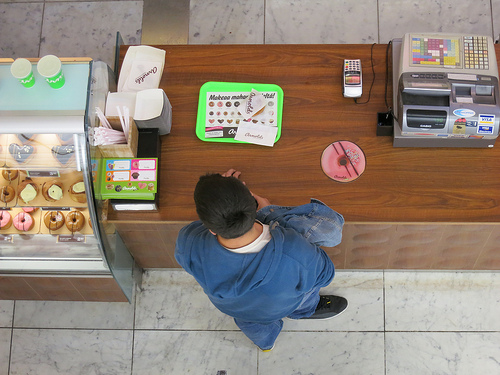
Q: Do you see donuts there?
A: Yes, there is a donut.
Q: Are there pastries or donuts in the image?
A: Yes, there is a donut.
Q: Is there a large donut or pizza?
A: Yes, there is a large donut.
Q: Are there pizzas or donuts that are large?
A: Yes, the donut is large.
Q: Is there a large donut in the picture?
A: Yes, there is a large donut.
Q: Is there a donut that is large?
A: Yes, there is a donut that is large.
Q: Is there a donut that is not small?
A: Yes, there is a large donut.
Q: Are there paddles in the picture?
A: No, there are no paddles.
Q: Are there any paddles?
A: No, there are no paddles.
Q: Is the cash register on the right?
A: Yes, the cash register is on the right of the image.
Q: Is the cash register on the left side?
A: No, the cash register is on the right of the image.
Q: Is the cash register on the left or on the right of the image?
A: The cash register is on the right of the image.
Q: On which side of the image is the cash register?
A: The cash register is on the right of the image.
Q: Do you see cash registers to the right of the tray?
A: Yes, there is a cash register to the right of the tray.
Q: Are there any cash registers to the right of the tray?
A: Yes, there is a cash register to the right of the tray.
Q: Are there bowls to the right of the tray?
A: No, there is a cash register to the right of the tray.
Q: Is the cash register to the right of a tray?
A: Yes, the cash register is to the right of a tray.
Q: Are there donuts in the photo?
A: Yes, there is a donut.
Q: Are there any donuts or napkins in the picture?
A: Yes, there is a donut.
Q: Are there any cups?
A: Yes, there is a cup.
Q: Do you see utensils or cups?
A: Yes, there is a cup.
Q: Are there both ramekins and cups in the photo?
A: No, there is a cup but no ramekins.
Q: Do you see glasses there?
A: No, there are no glasses.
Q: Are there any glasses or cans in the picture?
A: No, there are no glasses or cans.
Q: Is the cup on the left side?
A: Yes, the cup is on the left of the image.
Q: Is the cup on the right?
A: No, the cup is on the left of the image.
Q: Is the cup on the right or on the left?
A: The cup is on the left of the image.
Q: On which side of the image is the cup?
A: The cup is on the left of the image.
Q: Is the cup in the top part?
A: Yes, the cup is in the top of the image.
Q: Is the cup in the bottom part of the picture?
A: No, the cup is in the top of the image.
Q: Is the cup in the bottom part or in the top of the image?
A: The cup is in the top of the image.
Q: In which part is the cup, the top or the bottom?
A: The cup is in the top of the image.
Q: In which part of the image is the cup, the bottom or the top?
A: The cup is in the top of the image.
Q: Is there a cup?
A: Yes, there is a cup.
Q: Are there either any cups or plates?
A: Yes, there is a cup.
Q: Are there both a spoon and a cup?
A: No, there is a cup but no spoons.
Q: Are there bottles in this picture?
A: No, there are no bottles.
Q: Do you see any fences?
A: No, there are no fences.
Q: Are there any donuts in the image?
A: Yes, there is a donut.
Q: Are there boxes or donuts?
A: Yes, there is a donut.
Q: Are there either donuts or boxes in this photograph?
A: Yes, there is a donut.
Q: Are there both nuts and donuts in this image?
A: No, there is a donut but no nuts.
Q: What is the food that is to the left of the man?
A: The food is a donut.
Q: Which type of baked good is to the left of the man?
A: The food is a donut.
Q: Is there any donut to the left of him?
A: Yes, there is a donut to the left of the man.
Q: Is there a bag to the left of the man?
A: No, there is a donut to the left of the man.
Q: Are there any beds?
A: No, there are no beds.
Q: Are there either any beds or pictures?
A: No, there are no beds or pictures.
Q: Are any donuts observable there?
A: Yes, there is a donut.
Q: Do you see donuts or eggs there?
A: Yes, there is a donut.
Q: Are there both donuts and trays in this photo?
A: Yes, there are both a donut and a tray.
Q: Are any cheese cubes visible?
A: No, there are no cheese cubes.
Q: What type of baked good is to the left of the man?
A: The food is a donut.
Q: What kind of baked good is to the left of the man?
A: The food is a donut.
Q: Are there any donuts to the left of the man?
A: Yes, there is a donut to the left of the man.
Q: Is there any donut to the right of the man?
A: No, the donut is to the left of the man.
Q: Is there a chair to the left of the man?
A: No, there is a donut to the left of the man.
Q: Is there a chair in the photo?
A: No, there are no chairs.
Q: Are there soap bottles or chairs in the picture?
A: No, there are no chairs or soap bottles.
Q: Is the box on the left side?
A: Yes, the box is on the left of the image.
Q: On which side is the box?
A: The box is on the left of the image.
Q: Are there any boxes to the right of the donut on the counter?
A: Yes, there is a box to the right of the donut.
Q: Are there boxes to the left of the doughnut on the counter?
A: No, the box is to the right of the doughnut.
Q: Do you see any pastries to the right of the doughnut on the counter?
A: No, there is a box to the right of the donut.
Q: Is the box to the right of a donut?
A: Yes, the box is to the right of a donut.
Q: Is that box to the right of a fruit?
A: No, the box is to the right of a donut.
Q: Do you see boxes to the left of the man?
A: Yes, there is a box to the left of the man.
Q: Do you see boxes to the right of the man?
A: No, the box is to the left of the man.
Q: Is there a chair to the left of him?
A: No, there is a box to the left of the man.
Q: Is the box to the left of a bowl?
A: No, the box is to the left of the man.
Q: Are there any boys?
A: No, there are no boys.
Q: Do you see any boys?
A: No, there are no boys.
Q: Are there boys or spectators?
A: No, there are no boys or spectators.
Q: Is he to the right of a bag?
A: No, the man is to the right of the doughnut.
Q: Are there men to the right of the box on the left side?
A: Yes, there is a man to the right of the box.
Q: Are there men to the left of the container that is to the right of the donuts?
A: No, the man is to the right of the box.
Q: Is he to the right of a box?
A: Yes, the man is to the right of a box.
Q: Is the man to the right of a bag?
A: No, the man is to the right of a box.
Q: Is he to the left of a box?
A: No, the man is to the right of a box.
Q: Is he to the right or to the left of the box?
A: The man is to the right of the box.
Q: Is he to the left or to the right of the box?
A: The man is to the right of the box.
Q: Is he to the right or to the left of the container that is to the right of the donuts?
A: The man is to the right of the box.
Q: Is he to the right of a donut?
A: Yes, the man is to the right of a donut.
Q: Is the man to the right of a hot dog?
A: No, the man is to the right of a donut.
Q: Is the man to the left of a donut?
A: No, the man is to the right of a donut.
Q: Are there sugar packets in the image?
A: No, there are no sugar packets.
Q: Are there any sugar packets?
A: No, there are no sugar packets.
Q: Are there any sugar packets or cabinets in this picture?
A: No, there are no sugar packets or cabinets.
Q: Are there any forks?
A: No, there are no forks.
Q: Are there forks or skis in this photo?
A: No, there are no forks or skis.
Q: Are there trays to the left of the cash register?
A: Yes, there is a tray to the left of the cash register.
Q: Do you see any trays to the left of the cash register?
A: Yes, there is a tray to the left of the cash register.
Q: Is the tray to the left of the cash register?
A: Yes, the tray is to the left of the cash register.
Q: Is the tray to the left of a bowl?
A: No, the tray is to the left of the cash register.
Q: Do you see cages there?
A: No, there are no cages.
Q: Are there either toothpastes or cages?
A: No, there are no cages or toothpastes.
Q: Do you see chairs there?
A: No, there are no chairs.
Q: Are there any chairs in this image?
A: No, there are no chairs.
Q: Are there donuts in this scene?
A: Yes, there are donuts.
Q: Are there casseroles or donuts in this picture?
A: Yes, there are donuts.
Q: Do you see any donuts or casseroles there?
A: Yes, there are donuts.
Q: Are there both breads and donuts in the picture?
A: No, there are donuts but no breads.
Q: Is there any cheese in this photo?
A: No, there is no cheese.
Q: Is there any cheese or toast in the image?
A: No, there are no cheese or toasts.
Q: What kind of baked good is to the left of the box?
A: The food is donuts.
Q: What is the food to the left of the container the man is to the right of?
A: The food is donuts.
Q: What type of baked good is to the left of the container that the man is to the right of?
A: The food is donuts.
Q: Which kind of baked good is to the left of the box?
A: The food is donuts.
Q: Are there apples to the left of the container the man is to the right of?
A: No, there are donuts to the left of the box.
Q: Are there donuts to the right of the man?
A: No, the donuts are to the left of the man.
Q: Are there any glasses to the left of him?
A: No, there are donuts to the left of the man.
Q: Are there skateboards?
A: No, there are no skateboards.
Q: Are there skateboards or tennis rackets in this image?
A: No, there are no skateboards or tennis rackets.